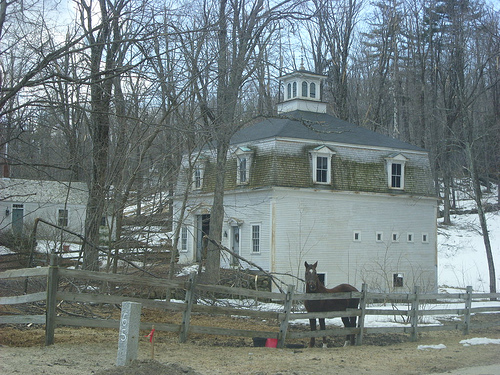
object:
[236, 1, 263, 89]
branch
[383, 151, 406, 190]
window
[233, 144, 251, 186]
window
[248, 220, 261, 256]
window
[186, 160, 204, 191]
window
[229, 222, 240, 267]
door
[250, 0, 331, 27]
branch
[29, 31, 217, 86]
branch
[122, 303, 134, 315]
marker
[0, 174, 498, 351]
snow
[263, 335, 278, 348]
buckets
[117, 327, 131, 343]
numbers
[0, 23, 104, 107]
branch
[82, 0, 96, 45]
branch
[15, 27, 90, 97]
branch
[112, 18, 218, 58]
branch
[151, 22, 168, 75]
branch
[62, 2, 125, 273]
tree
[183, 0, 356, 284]
tree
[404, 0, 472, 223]
tree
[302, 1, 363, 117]
tree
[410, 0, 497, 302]
tree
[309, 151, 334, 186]
window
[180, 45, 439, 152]
roof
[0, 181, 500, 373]
barn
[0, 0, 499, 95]
sky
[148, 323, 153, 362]
post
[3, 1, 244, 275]
tree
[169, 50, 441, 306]
building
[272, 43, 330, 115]
steeple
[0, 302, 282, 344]
grass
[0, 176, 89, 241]
building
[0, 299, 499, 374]
ground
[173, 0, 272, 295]
tree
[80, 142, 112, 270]
branch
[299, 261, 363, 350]
horse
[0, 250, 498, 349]
fence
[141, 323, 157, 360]
flag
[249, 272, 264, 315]
stick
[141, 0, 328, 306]
tree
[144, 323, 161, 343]
marker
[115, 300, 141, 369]
post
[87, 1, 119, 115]
branch